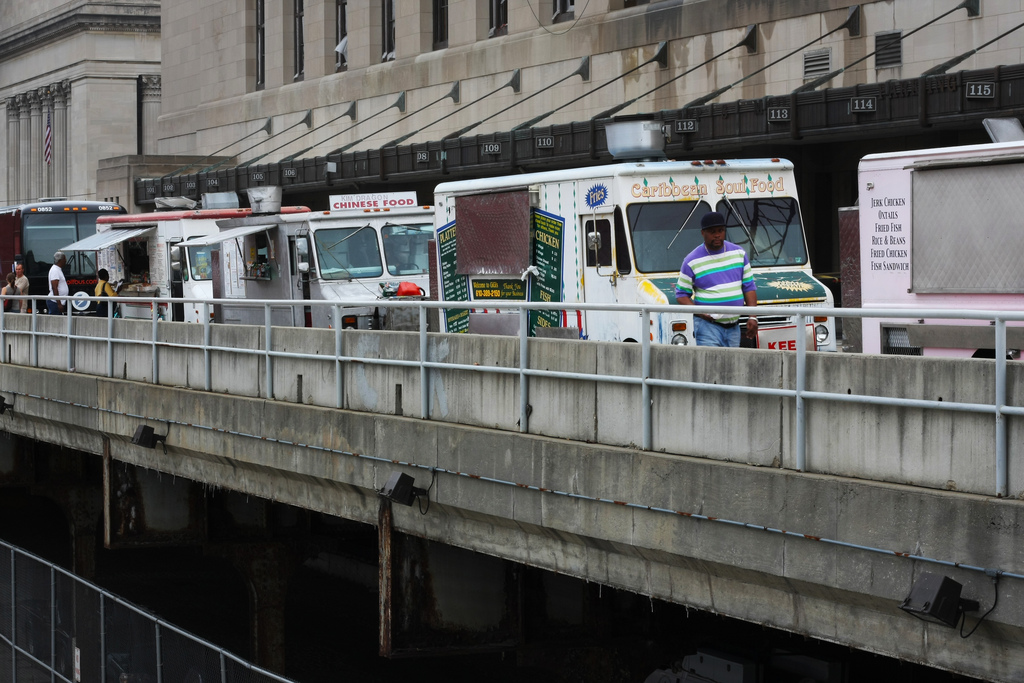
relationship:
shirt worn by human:
[682, 251, 750, 309] [682, 204, 752, 309]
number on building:
[958, 74, 998, 97] [773, 7, 999, 159]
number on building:
[848, 94, 876, 114] [764, 38, 939, 176]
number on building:
[764, 99, 793, 125] [591, 33, 873, 171]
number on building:
[666, 114, 714, 134] [540, 13, 820, 165]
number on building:
[654, 112, 703, 136] [498, 16, 835, 173]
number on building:
[523, 127, 568, 151] [366, 25, 567, 152]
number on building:
[467, 127, 516, 154] [381, 19, 884, 190]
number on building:
[407, 142, 433, 169] [318, 13, 942, 247]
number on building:
[282, 164, 298, 178] [281, 0, 624, 177]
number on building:
[245, 161, 275, 181] [245, 4, 505, 181]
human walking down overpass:
[673, 204, 765, 347] [0, 263, 1016, 679]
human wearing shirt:
[673, 204, 765, 347] [677, 237, 758, 326]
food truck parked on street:
[423, 171, 825, 372] [641, 302, 933, 518]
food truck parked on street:
[211, 197, 453, 341] [0, 243, 1024, 531]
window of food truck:
[454, 187, 537, 281] [424, 151, 841, 348]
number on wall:
[848, 94, 876, 114] [150, 6, 1021, 380]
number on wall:
[675, 101, 706, 136] [139, 0, 1021, 417]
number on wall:
[496, 114, 580, 165] [150, 6, 1021, 380]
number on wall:
[409, 142, 433, 162] [510, 43, 643, 130]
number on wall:
[848, 94, 876, 114] [793, 89, 929, 124]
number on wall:
[282, 164, 298, 178] [133, 61, 1022, 205]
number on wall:
[671, 115, 698, 132] [133, 61, 1022, 205]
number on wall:
[764, 99, 792, 125] [133, 61, 1022, 205]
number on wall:
[848, 93, 877, 113] [133, 61, 1022, 205]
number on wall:
[961, 79, 997, 100] [133, 61, 1022, 205]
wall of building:
[150, 6, 1021, 380] [171, 14, 962, 202]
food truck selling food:
[60, 206, 258, 315] [31, 258, 155, 326]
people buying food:
[1, 245, 142, 318] [40, 258, 159, 297]